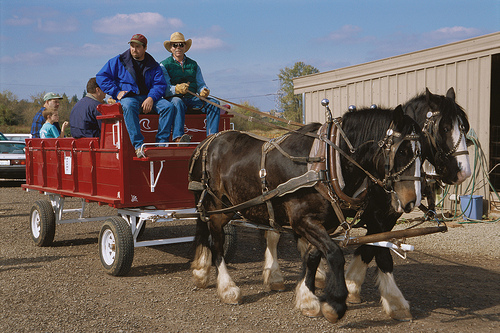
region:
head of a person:
[162, 25, 193, 57]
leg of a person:
[119, 89, 146, 143]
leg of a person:
[152, 92, 184, 134]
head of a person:
[37, 108, 65, 119]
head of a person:
[69, 66, 116, 108]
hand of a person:
[112, 85, 137, 105]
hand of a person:
[140, 86, 160, 114]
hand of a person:
[176, 76, 201, 94]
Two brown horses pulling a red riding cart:
[18, 31, 475, 331]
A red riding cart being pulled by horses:
[13, 94, 233, 279]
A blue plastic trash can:
[455, 195, 485, 220]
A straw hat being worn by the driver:
[163, 30, 196, 54]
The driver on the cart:
[158, 30, 225, 143]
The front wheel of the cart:
[95, 217, 137, 274]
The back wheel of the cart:
[21, 199, 56, 248]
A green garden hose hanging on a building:
[438, 130, 485, 222]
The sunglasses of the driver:
[170, 42, 184, 52]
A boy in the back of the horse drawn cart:
[35, 107, 70, 139]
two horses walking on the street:
[189, 80, 488, 325]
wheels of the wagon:
[13, 196, 165, 278]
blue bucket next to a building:
[457, 191, 480, 222]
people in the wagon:
[25, 30, 200, 187]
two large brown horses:
[184, 91, 479, 326]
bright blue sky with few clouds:
[3, 6, 498, 116]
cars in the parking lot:
[1, 132, 46, 183]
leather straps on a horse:
[190, 100, 355, 217]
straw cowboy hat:
[163, 27, 195, 56]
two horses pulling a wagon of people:
[183, 89, 482, 319]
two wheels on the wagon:
[23, 195, 142, 275]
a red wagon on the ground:
[22, 106, 233, 235]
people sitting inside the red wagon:
[30, 28, 202, 163]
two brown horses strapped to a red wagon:
[22, 77, 482, 307]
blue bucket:
[455, 192, 485, 226]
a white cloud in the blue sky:
[102, 12, 199, 41]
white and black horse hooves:
[192, 248, 420, 323]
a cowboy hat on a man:
[164, 28, 194, 53]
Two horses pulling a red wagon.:
[23, 86, 470, 322]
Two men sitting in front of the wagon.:
[97, 32, 223, 154]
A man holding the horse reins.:
[173, 82, 437, 187]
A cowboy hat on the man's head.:
[160, 32, 195, 51]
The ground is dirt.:
[0, 183, 499, 332]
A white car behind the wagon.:
[0, 139, 30, 176]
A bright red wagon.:
[21, 102, 236, 210]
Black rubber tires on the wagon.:
[28, 200, 135, 275]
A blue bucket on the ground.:
[458, 193, 484, 223]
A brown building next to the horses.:
[291, 36, 499, 221]